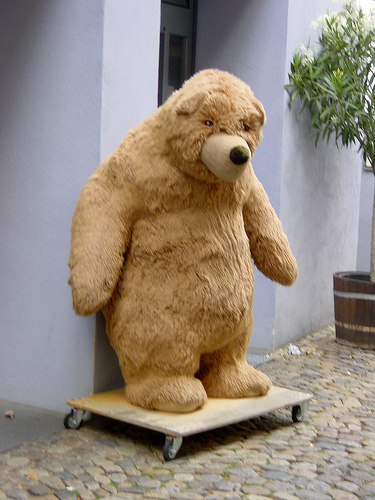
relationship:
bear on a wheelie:
[63, 73, 318, 409] [57, 389, 310, 462]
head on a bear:
[160, 65, 267, 186] [66, 67, 299, 415]